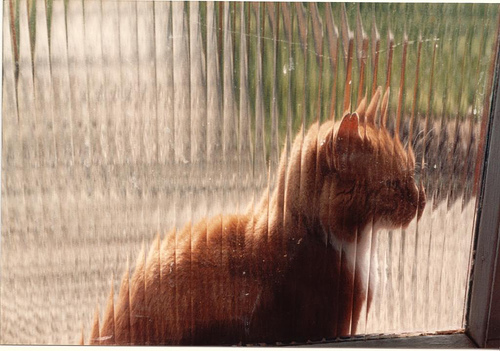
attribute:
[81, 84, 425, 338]
cat — tan, standing, motionless, orange, sitting, staring, white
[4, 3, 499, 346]
window — frosted, textured, lined, ribbed pattern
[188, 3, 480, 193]
grass — green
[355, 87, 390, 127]
ears — pointed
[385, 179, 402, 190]
eyes — green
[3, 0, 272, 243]
background — white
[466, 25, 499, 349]
door — grey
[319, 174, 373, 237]
fur — ruffled, white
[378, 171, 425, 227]
face — serious